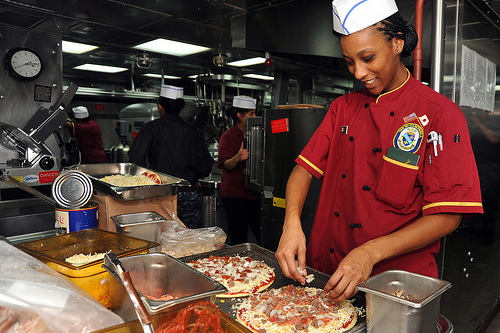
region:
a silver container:
[337, 259, 451, 331]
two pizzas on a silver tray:
[186, 243, 381, 331]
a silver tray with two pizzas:
[171, 230, 388, 331]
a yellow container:
[17, 209, 187, 321]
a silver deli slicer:
[2, 85, 107, 212]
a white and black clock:
[1, 35, 48, 84]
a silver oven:
[222, 76, 372, 258]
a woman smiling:
[326, 3, 404, 108]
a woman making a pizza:
[236, 8, 479, 330]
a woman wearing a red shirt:
[326, 2, 458, 322]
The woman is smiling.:
[319, 0, 436, 111]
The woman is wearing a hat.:
[320, 0, 429, 101]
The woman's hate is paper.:
[326, 0, 424, 101]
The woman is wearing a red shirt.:
[273, 0, 489, 300]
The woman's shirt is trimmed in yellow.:
[268, 0, 491, 277]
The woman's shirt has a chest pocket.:
[272, 0, 487, 306]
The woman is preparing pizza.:
[176, 1, 483, 331]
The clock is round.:
[1, 38, 46, 88]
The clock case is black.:
[3, 41, 49, 89]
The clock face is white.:
[3, 38, 48, 86]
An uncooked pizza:
[242, 284, 358, 331]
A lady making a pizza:
[265, 1, 478, 331]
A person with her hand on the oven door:
[216, 90, 280, 245]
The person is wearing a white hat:
[131, 81, 215, 221]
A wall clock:
[5, 48, 45, 80]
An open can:
[52, 167, 97, 237]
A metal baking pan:
[73, 159, 189, 196]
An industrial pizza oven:
[256, 103, 318, 258]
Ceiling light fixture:
[133, 35, 213, 57]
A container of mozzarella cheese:
[25, 225, 156, 301]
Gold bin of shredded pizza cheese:
[44, 223, 144, 298]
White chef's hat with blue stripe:
[318, 0, 398, 34]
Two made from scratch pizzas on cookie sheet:
[181, 230, 362, 331]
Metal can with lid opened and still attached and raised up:
[49, 163, 98, 232]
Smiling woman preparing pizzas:
[251, 0, 488, 301]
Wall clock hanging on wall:
[7, 33, 49, 91]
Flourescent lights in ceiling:
[53, 17, 293, 97]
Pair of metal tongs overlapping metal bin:
[93, 238, 155, 331]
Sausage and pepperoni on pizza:
[248, 286, 340, 329]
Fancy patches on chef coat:
[378, 108, 443, 170]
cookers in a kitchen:
[13, 5, 485, 327]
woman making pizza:
[213, 0, 480, 331]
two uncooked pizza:
[187, 248, 370, 331]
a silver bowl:
[351, 263, 458, 331]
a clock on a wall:
[8, 33, 48, 90]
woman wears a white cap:
[311, 0, 458, 160]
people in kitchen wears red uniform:
[6, 4, 491, 284]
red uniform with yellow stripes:
[298, 77, 486, 280]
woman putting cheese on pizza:
[234, 0, 476, 331]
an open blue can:
[43, 165, 105, 233]